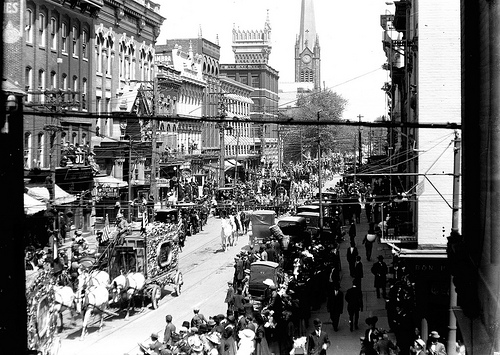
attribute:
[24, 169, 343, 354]
road — center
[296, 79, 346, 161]
tree — distant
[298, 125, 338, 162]
tree — distant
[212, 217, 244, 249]
horse — pulling